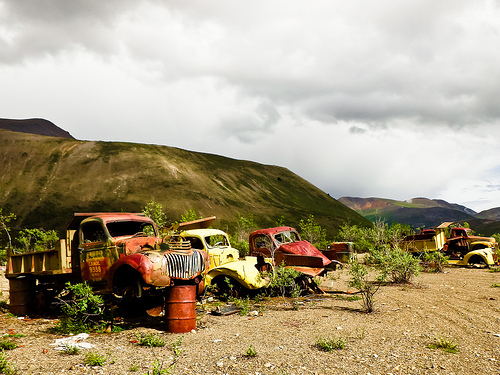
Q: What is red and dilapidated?
A: A truck.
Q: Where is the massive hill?
A: It's in the ground.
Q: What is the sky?
A: Grey and cloudy.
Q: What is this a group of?
A: Three broken down vehicles.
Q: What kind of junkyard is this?
A: Old vehicles.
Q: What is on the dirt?
A: Several old trucks.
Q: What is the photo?
A: Several old broken trucks.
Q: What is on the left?
A: Front of an old broken truck.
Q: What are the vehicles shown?
A: Trucks.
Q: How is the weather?
A: Cloudy.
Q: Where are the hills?
A: Background.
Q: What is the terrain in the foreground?
A: Sandy desert.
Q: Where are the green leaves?
A: Trees.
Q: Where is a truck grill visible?
A: Above can.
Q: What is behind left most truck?
A: Bed.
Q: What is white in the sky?
A: Clouds.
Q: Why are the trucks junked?
A: Old and in disrepair.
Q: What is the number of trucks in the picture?
A: Five.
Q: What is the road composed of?
A: Gravel.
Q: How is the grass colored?
A: Green.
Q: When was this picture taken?
A: Day time.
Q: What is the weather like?
A: Cloudy.